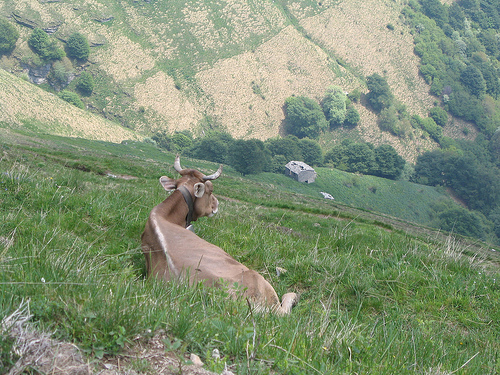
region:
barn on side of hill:
[277, 156, 324, 189]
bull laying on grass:
[130, 140, 310, 330]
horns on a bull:
[162, 143, 240, 188]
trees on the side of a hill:
[0, 15, 111, 110]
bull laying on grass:
[124, 145, 320, 338]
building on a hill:
[277, 155, 348, 213]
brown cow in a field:
[125, 137, 310, 329]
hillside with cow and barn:
[3, 3, 487, 363]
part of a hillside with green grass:
[304, 216, 409, 373]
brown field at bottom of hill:
[182, 44, 402, 151]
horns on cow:
[158, 150, 233, 183]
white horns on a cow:
[162, 144, 235, 186]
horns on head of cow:
[148, 145, 235, 214]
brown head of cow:
[170, 155, 227, 225]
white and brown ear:
[155, 169, 175, 195]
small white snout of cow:
[207, 198, 222, 215]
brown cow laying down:
[110, 156, 296, 316]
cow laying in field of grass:
[104, 135, 293, 335]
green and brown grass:
[290, 235, 370, 322]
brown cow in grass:
[140, 154, 296, 325]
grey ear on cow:
[158, 174, 174, 193]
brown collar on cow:
[178, 185, 196, 225]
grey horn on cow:
[208, 164, 223, 182]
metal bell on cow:
[186, 224, 194, 234]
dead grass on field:
[5, 305, 181, 374]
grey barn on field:
[284, 160, 318, 185]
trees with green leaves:
[173, 132, 324, 176]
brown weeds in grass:
[441, 227, 488, 264]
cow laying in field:
[139, 153, 298, 314]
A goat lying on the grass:
[147, 154, 226, 283]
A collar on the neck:
[185, 191, 189, 198]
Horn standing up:
[175, 157, 180, 167]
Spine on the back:
[155, 226, 160, 233]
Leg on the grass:
[283, 294, 293, 303]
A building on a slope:
[291, 161, 308, 178]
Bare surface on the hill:
[219, 78, 234, 94]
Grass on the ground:
[352, 269, 412, 299]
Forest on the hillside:
[444, 47, 498, 84]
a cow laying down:
[108, 141, 362, 374]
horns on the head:
[166, 147, 242, 198]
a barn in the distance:
[282, 146, 322, 201]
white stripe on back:
[147, 198, 179, 290]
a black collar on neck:
[166, 177, 198, 224]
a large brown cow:
[108, 124, 322, 367]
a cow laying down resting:
[90, 149, 365, 360]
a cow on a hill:
[91, 124, 378, 361]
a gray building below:
[281, 144, 353, 209]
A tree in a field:
[371, 142, 404, 179]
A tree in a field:
[287, 93, 329, 134]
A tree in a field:
[326, 81, 348, 123]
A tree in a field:
[364, 72, 384, 104]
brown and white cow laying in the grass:
[130, 143, 302, 325]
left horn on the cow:
[170, 152, 188, 172]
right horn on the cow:
[200, 163, 227, 182]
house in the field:
[278, 155, 320, 190]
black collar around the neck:
[175, 185, 192, 204]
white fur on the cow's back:
[152, 220, 172, 259]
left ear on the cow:
[160, 172, 174, 192]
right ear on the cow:
[191, 178, 205, 200]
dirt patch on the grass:
[84, 338, 178, 374]